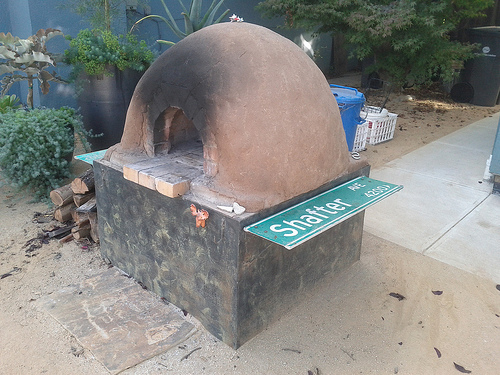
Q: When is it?
A: Day time.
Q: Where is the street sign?
A: By the smoker.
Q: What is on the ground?
A: Sand.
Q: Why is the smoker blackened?
A: From cooking things.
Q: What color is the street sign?
A: Green.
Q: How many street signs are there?
A: One.